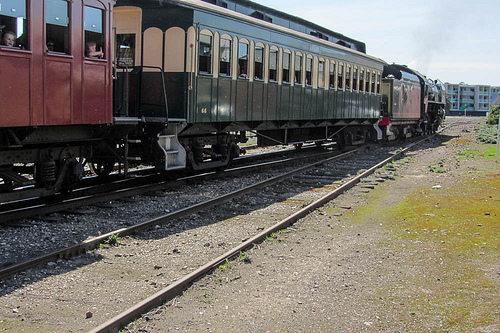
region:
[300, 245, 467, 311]
The ground is made of asphalt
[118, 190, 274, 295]
The train tracks on the ground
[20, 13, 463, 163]
The train on the train tracks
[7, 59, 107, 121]
The train is the color red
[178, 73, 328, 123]
The train is the color green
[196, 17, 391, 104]
The windows on the side of the train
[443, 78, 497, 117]
The apartment building on the ground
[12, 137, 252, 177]
The feet of the train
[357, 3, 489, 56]
The sky is clear and blue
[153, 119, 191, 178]
The stairs on the train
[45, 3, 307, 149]
this is the train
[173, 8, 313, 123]
the road is green in color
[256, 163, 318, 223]
these are the rails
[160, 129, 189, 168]
this is the staircase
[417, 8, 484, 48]
this is the sky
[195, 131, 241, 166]
these are the wheels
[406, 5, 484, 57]
the sky is blue in color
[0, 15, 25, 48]
this is the window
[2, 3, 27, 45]
the window is closed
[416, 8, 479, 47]
the sky is clear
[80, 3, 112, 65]
The window is rectangular.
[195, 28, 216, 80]
The window is rectangular.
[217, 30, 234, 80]
The window is rectangular.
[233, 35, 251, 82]
The window is rectangular.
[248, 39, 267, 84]
The window is rectangular.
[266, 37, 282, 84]
The window is rectangular.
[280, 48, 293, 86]
The window is rectangular.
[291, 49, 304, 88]
The window is rectangular.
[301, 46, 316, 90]
The window is rectangular.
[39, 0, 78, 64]
The window is rectangular.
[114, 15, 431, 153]
train car is cream and green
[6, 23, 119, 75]
kids in the train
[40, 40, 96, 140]
this car is red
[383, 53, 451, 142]
the train engines up front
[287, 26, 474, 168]
train on the tracks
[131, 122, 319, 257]
gravel is grey between rails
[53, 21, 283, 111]
a red train car and a green one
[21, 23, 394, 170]
this is a passenger train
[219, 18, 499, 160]
train headed past building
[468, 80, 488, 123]
the building is white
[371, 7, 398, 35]
the sky has clouds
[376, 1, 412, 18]
the sky is blue in color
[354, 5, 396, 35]
the clouds are white in color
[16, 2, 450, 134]
this is a train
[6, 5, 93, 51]
this is a window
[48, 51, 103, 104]
the train is red in color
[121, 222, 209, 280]
this is a railway line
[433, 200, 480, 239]
this is the ground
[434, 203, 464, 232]
the ground is green in color